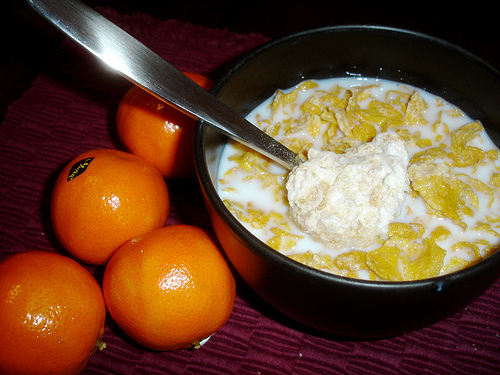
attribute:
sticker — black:
[66, 156, 95, 183]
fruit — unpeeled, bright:
[47, 147, 170, 265]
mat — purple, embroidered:
[0, 5, 499, 374]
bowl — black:
[192, 22, 500, 342]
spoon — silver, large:
[27, 0, 304, 173]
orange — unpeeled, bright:
[100, 221, 238, 351]